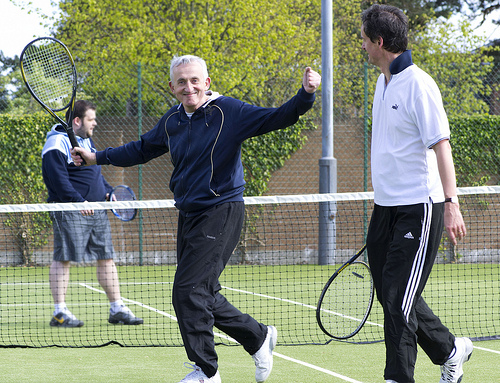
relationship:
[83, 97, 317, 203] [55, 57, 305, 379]
jacket on man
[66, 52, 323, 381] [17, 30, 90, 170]
man playing tennis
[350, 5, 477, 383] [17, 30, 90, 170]
man playing tennis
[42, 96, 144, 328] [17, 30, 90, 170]
man playing tennis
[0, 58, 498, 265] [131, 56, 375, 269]
fence with post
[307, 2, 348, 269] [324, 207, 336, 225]
post with bolt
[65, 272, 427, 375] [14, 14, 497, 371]
lines on court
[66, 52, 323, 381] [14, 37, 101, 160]
man holding tennis racket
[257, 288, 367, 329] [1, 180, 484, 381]
lines on tennis court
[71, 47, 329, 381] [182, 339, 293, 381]
man wears white shoes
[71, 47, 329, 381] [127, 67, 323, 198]
man wears shirt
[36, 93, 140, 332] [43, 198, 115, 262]
man wears shorts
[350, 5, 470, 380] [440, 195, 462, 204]
man wearing watch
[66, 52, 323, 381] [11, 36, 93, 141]
man wearing sweatshirt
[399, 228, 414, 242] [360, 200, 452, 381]
adidas logo on man's pants